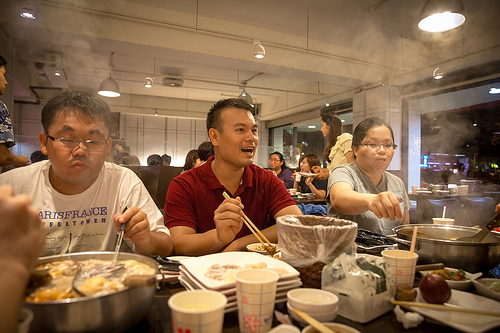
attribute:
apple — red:
[420, 272, 451, 304]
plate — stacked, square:
[180, 251, 300, 292]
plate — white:
[395, 281, 500, 330]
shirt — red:
[166, 154, 294, 239]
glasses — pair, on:
[358, 140, 398, 153]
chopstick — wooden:
[221, 188, 275, 250]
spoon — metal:
[113, 208, 128, 268]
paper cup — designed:
[379, 247, 418, 296]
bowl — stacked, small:
[287, 286, 339, 311]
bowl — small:
[285, 301, 339, 327]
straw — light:
[409, 225, 417, 256]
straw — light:
[443, 204, 447, 218]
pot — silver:
[391, 224, 498, 266]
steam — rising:
[315, 11, 480, 207]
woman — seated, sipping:
[292, 154, 328, 198]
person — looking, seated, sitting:
[2, 84, 174, 257]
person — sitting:
[166, 97, 302, 254]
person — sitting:
[326, 115, 412, 234]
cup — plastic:
[458, 183, 468, 195]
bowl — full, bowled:
[22, 251, 162, 327]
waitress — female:
[315, 110, 353, 180]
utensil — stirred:
[396, 215, 409, 238]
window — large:
[285, 125, 354, 166]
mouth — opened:
[241, 145, 255, 153]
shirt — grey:
[326, 162, 411, 236]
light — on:
[419, 1, 465, 32]